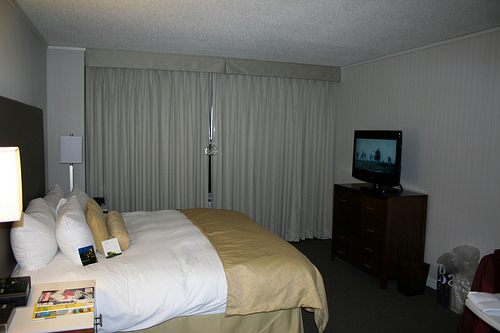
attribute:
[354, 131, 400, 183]
tv — black, on, flat screened, flat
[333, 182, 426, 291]
chest — brown, wood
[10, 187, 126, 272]
pillows — white, stacked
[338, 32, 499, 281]
wall — white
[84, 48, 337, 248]
curtains — long, hung, white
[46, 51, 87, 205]
wall — narrow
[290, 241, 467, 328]
floor — brown, carpeted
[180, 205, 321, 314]
cover — tan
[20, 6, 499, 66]
ceiling — above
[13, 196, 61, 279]
pillow — edged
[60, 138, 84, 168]
shade — square, white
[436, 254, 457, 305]
bag — shopping, Bass store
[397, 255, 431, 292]
trashcan — small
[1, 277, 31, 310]
clock — black